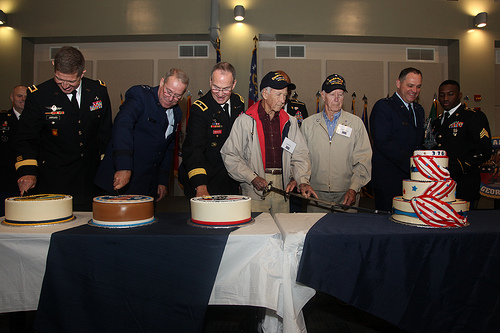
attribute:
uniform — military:
[439, 107, 494, 204]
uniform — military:
[322, 72, 343, 89]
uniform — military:
[264, 71, 293, 86]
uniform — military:
[185, 100, 240, 192]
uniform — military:
[18, 91, 110, 194]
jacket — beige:
[227, 127, 258, 167]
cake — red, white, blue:
[392, 146, 472, 224]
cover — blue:
[329, 213, 446, 313]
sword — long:
[255, 178, 387, 218]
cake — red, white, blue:
[387, 147, 471, 228]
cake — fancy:
[397, 136, 471, 232]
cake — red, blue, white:
[391, 149, 468, 226]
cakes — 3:
[1, 174, 309, 246]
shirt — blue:
[321, 111, 340, 141]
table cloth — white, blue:
[0, 200, 497, 331]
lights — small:
[227, 6, 494, 33]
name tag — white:
[330, 116, 356, 151]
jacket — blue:
[97, 86, 185, 194]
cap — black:
[317, 70, 348, 92]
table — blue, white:
[1, 206, 484, 327]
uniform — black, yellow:
[13, 79, 114, 203]